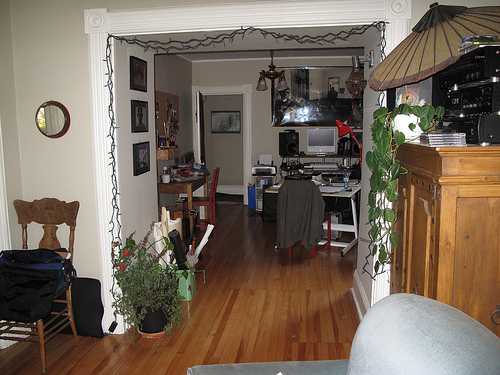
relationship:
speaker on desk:
[278, 131, 300, 156] [279, 150, 362, 182]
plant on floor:
[110, 220, 195, 348] [0, 194, 357, 373]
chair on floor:
[2, 197, 79, 374] [0, 194, 357, 373]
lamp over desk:
[335, 121, 362, 163] [279, 150, 362, 182]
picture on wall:
[208, 110, 242, 134] [200, 95, 244, 186]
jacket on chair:
[274, 180, 323, 249] [276, 178, 331, 259]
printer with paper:
[251, 154, 277, 176] [257, 154, 272, 167]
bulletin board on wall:
[155, 90, 179, 153] [154, 54, 192, 235]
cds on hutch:
[419, 131, 467, 147] [388, 139, 499, 339]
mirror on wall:
[36, 100, 71, 139] [0, 1, 99, 301]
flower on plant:
[118, 262, 125, 271] [110, 220, 195, 348]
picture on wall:
[128, 53, 149, 92] [112, 37, 158, 332]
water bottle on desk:
[342, 170, 350, 192] [265, 180, 361, 258]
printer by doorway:
[251, 154, 277, 176] [190, 85, 253, 219]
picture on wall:
[132, 143, 151, 176] [112, 37, 158, 332]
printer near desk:
[251, 154, 277, 176] [279, 150, 362, 182]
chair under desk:
[276, 178, 331, 259] [265, 180, 361, 258]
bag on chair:
[0, 248, 75, 323] [2, 197, 79, 374]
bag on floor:
[38, 277, 103, 337] [0, 194, 357, 373]